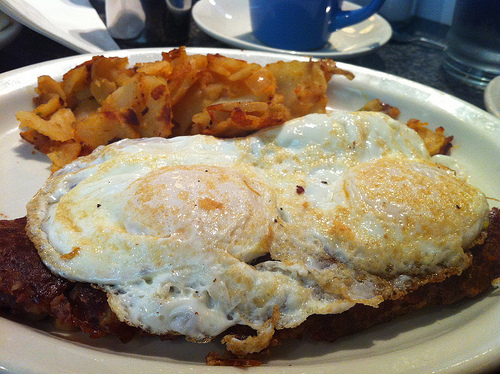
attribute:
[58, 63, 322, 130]
potatoes — fried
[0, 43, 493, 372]
plate — white, ceramic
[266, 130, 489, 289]
egg — fried, over easy, cooked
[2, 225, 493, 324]
meat — brown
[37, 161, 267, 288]
egg — fried, cooked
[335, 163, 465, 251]
yolk — yellow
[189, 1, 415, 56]
saucer — white, ceramic, round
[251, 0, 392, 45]
mug — blue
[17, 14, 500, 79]
table — grey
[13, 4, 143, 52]
napkin — white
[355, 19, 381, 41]
light — shining